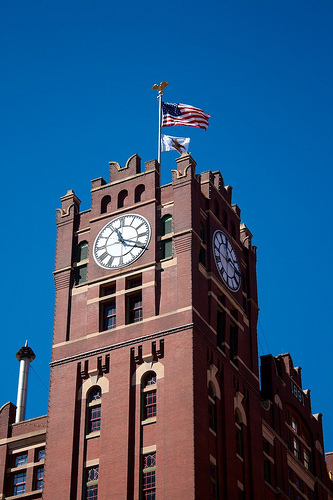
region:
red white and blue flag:
[151, 97, 212, 130]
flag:
[154, 127, 197, 153]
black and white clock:
[80, 210, 156, 260]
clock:
[206, 229, 246, 303]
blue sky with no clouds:
[12, 13, 61, 68]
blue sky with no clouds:
[33, 74, 83, 126]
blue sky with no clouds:
[85, 72, 121, 138]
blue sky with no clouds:
[269, 149, 314, 200]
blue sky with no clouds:
[0, 108, 52, 159]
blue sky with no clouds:
[219, 8, 277, 87]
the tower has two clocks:
[94, 215, 241, 293]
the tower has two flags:
[163, 97, 210, 156]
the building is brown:
[0, 153, 332, 498]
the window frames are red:
[1, 301, 331, 498]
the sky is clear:
[0, 0, 331, 454]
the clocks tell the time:
[95, 213, 240, 292]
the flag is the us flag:
[162, 102, 209, 131]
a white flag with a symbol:
[162, 133, 189, 155]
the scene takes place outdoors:
[1, 0, 330, 499]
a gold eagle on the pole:
[154, 82, 167, 90]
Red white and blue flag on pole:
[155, 94, 221, 144]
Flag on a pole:
[151, 131, 217, 163]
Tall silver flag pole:
[147, 82, 164, 160]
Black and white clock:
[84, 215, 152, 292]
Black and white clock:
[206, 222, 243, 306]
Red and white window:
[72, 396, 104, 435]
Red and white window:
[129, 370, 160, 429]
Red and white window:
[134, 451, 170, 497]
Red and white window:
[72, 457, 104, 499]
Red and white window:
[24, 442, 50, 494]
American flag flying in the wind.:
[160, 99, 209, 131]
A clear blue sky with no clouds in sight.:
[0, 0, 332, 460]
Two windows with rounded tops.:
[85, 368, 157, 437]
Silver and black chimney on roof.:
[12, 338, 35, 422]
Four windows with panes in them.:
[6, 446, 43, 492]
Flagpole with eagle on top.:
[151, 79, 171, 164]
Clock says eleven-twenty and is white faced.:
[91, 211, 150, 268]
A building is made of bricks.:
[0, 149, 331, 498]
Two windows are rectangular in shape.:
[96, 271, 141, 334]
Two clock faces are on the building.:
[70, 211, 240, 290]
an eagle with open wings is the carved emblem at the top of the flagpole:
[148, 78, 170, 101]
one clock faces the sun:
[93, 206, 151, 276]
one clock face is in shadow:
[212, 226, 252, 295]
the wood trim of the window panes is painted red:
[82, 384, 160, 496]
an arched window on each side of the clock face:
[64, 203, 177, 294]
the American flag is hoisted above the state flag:
[143, 92, 212, 180]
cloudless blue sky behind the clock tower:
[1, 72, 331, 433]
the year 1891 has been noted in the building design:
[285, 376, 313, 409]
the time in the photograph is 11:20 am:
[86, 205, 150, 281]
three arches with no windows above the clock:
[93, 179, 154, 216]